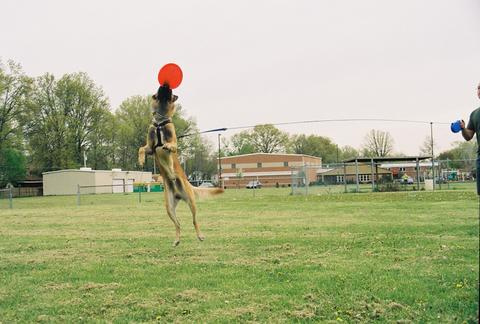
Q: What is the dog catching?
A: Frisbee.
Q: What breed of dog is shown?
A: German shepherd.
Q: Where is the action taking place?
A: In a field.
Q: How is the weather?
A: Grey and overcast.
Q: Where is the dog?
A: In the air.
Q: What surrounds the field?
A: Chain link fence.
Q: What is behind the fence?
A: Buildings.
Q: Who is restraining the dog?
A: A man.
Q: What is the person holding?
A: A leash.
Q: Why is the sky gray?
A: Cloudy.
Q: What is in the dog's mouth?
A: Frisbee.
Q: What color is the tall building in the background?
A: Red.